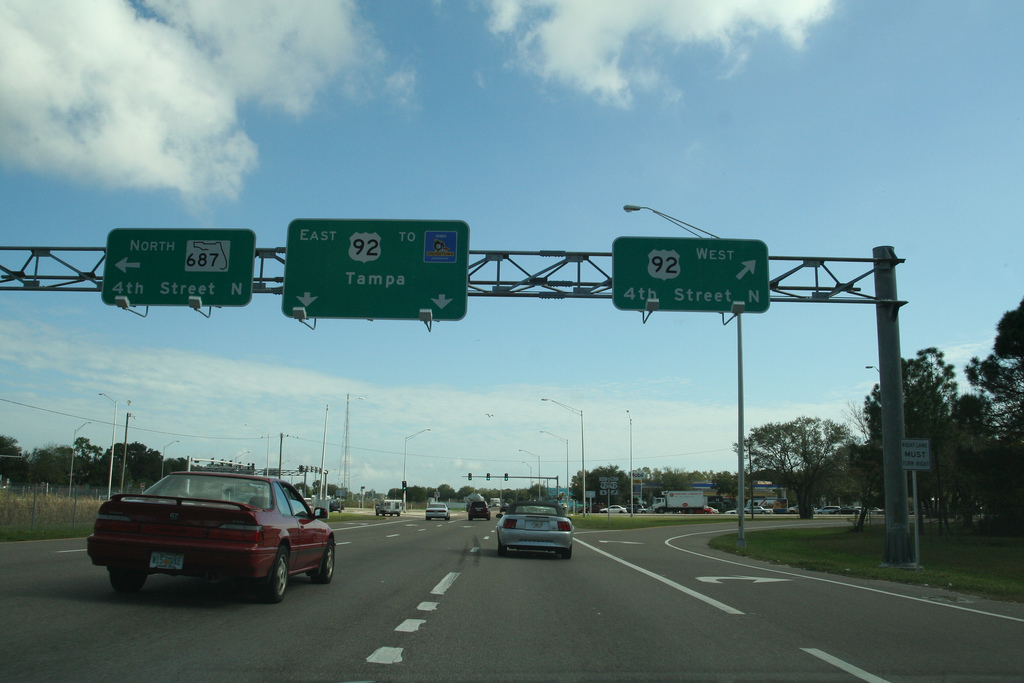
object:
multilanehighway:
[0, 480, 1024, 683]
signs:
[101, 219, 767, 319]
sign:
[610, 237, 771, 313]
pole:
[873, 245, 912, 565]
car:
[85, 470, 335, 604]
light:
[468, 473, 473, 481]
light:
[485, 473, 490, 480]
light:
[504, 473, 509, 482]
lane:
[583, 509, 1024, 683]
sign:
[901, 438, 929, 470]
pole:
[911, 467, 922, 574]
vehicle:
[599, 505, 627, 513]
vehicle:
[651, 489, 705, 514]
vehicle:
[736, 505, 774, 514]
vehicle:
[814, 505, 842, 516]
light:
[299, 464, 329, 475]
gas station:
[636, 474, 776, 509]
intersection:
[332, 490, 594, 530]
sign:
[287, 220, 468, 319]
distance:
[331, 498, 630, 571]